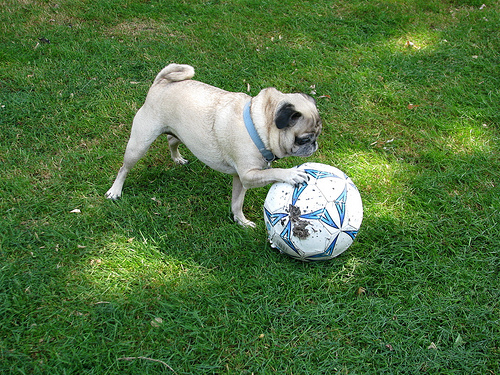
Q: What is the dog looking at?
A: A ball.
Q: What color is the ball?
A: Blue and white.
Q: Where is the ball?
A: On the grass.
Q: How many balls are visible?
A: One.